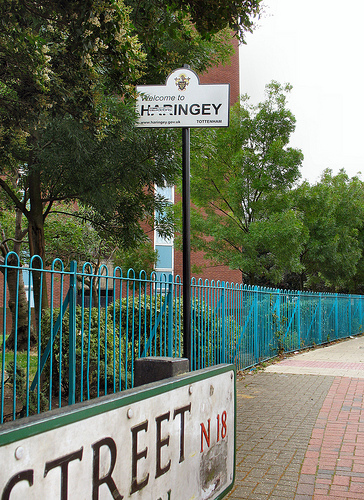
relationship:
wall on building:
[1, 1, 243, 349] [2, 1, 246, 355]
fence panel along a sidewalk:
[4, 244, 363, 430] [147, 334, 363, 496]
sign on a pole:
[118, 62, 239, 136] [178, 125, 198, 367]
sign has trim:
[118, 62, 239, 136] [133, 69, 231, 129]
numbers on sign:
[215, 411, 227, 443] [5, 359, 237, 499]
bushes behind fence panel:
[37, 293, 355, 392] [4, 244, 363, 430]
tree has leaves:
[0, 1, 262, 344] [0, 0, 267, 210]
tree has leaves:
[172, 77, 306, 352] [186, 80, 308, 272]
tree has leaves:
[288, 165, 361, 338] [271, 170, 362, 296]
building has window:
[2, 1, 246, 355] [149, 142, 177, 295]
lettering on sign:
[200, 409, 230, 451] [5, 359, 237, 499]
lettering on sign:
[139, 94, 226, 126] [118, 62, 239, 136]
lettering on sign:
[3, 397, 197, 499] [5, 359, 237, 499]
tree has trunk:
[0, 1, 262, 344] [20, 159, 61, 382]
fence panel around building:
[4, 244, 363, 430] [2, 1, 246, 355]